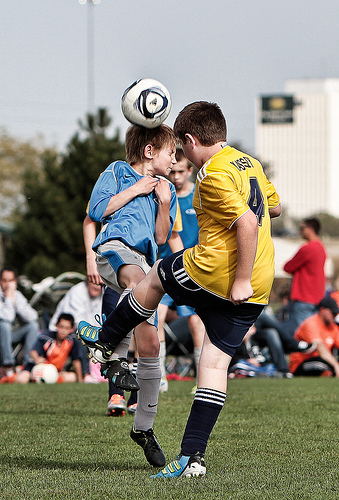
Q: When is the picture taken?
A: Daytime.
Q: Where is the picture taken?
A: At a soccer game.